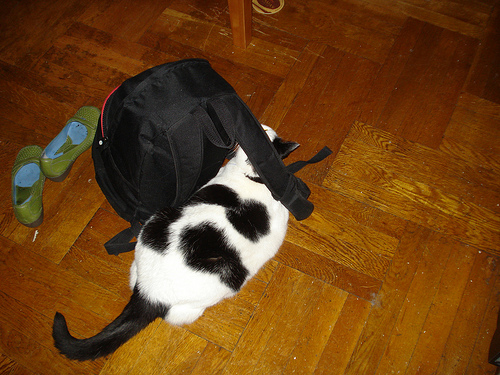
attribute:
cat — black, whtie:
[65, 167, 257, 348]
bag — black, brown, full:
[123, 75, 219, 166]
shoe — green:
[11, 135, 39, 216]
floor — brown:
[397, 73, 463, 161]